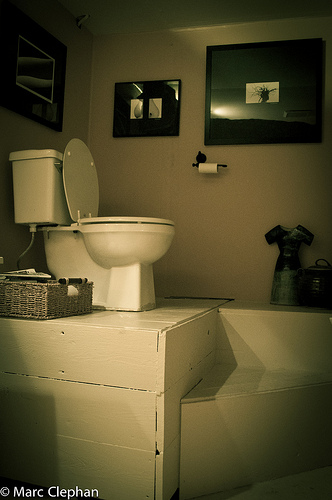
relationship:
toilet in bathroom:
[8, 143, 173, 306] [1, 9, 325, 497]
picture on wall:
[197, 38, 332, 144] [4, 0, 326, 301]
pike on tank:
[1, 45, 58, 138] [13, 151, 58, 225]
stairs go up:
[159, 308, 323, 476] [174, 293, 290, 398]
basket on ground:
[1, 262, 94, 326] [22, 277, 174, 376]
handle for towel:
[214, 161, 236, 173] [190, 159, 229, 175]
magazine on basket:
[11, 263, 55, 289] [1, 262, 94, 326]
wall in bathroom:
[4, 0, 326, 301] [1, 9, 325, 497]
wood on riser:
[77, 345, 233, 442] [143, 324, 322, 383]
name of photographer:
[6, 478, 82, 499] [6, 490, 94, 498]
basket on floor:
[1, 262, 94, 326] [18, 278, 328, 344]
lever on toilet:
[53, 160, 65, 172] [8, 143, 173, 306]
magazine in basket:
[0, 268, 51, 279] [1, 262, 94, 326]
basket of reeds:
[1, 262, 94, 326] [11, 274, 91, 313]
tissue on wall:
[197, 160, 226, 172] [4, 0, 326, 301]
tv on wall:
[197, 38, 332, 144] [4, 0, 326, 301]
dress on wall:
[257, 222, 326, 307] [4, 0, 326, 301]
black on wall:
[110, 83, 197, 128] [4, 0, 326, 301]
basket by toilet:
[1, 262, 94, 326] [8, 143, 173, 306]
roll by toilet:
[186, 159, 225, 183] [8, 143, 173, 306]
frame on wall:
[107, 80, 181, 149] [4, 0, 326, 301]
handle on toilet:
[214, 161, 236, 173] [8, 143, 173, 306]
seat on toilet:
[58, 132, 186, 239] [8, 143, 173, 306]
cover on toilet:
[17, 152, 56, 162] [8, 143, 173, 306]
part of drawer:
[1, 323, 164, 398] [1, 390, 152, 499]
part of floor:
[1, 323, 164, 398] [18, 278, 328, 344]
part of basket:
[1, 323, 164, 398] [1, 262, 94, 326]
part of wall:
[1, 323, 164, 398] [4, 0, 326, 301]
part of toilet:
[1, 323, 164, 398] [8, 143, 173, 306]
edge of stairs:
[190, 280, 259, 309] [159, 308, 323, 476]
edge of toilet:
[190, 280, 259, 309] [8, 143, 173, 306]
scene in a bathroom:
[1, 9, 325, 497] [76, 362, 269, 466]